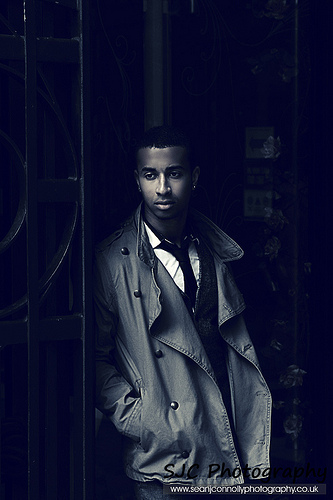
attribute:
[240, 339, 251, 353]
hole — button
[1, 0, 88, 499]
gate — iron, decorative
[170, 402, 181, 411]
button — Gray 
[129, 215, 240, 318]
shirt — white 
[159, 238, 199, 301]
tie — black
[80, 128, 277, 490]
male — black, young, adult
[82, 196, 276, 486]
coat — gray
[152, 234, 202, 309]
tie — black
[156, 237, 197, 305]
tie — black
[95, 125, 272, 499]
male — young, adult, professional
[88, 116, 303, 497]
male — young, adult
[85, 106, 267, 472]
male — young, adult, black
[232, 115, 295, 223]
sign — reflecting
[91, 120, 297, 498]
man — leaning, standing